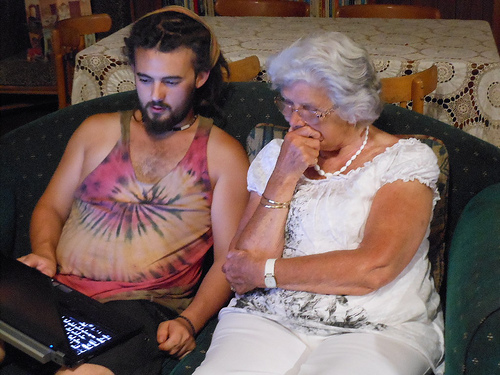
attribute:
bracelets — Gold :
[263, 196, 296, 213]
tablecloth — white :
[69, 8, 499, 153]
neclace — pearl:
[310, 124, 372, 179]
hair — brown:
[120, 10, 232, 135]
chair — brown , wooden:
[40, 14, 120, 106]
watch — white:
[263, 243, 280, 294]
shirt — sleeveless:
[53, 119, 208, 282]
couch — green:
[5, 82, 497, 374]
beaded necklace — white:
[313, 126, 368, 176]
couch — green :
[15, 60, 491, 348]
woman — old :
[204, 35, 463, 369]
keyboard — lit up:
[52, 309, 113, 353]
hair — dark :
[125, 14, 221, 122]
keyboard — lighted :
[44, 298, 114, 358]